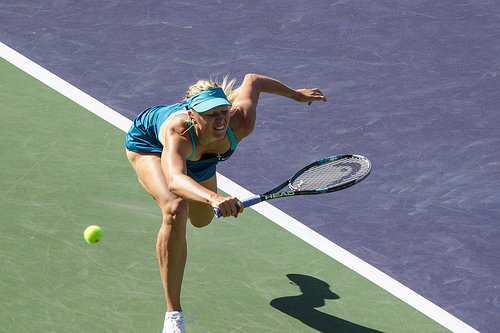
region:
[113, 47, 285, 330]
this is a person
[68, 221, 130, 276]
this is a ball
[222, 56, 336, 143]
this is a hand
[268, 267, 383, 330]
this is a shadow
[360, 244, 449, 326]
this is a line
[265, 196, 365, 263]
this is a line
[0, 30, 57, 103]
this is a line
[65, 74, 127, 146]
this is a line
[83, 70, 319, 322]
this is a person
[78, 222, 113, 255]
this is a ball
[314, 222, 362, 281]
a line on the road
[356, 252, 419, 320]
a line on the road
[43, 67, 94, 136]
a line on the road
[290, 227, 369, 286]
a line on the road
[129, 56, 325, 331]
A woman playing tennis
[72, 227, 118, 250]
A small green tennis ball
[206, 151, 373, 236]
A nlue handle tennis racket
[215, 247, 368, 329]
A green tennis court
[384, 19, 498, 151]
A grey tennis court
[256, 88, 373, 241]
A grey tennis court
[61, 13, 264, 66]
A grey tennis court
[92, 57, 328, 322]
this is a lady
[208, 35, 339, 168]
the hand of a lady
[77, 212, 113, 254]
this is a ball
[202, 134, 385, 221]
this is a racket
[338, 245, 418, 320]
a white line on the road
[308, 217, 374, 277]
a white line on the road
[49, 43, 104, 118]
a white line on the road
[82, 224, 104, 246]
green tennis ball in air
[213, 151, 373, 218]
tennis racket in woman's hand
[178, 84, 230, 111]
blue sun visor on woman's head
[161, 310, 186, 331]
white tennis shoe on woman's foot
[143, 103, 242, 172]
blue tank top shirt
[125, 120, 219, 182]
blue shorts on woman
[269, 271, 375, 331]
shadow of woman being cast on ground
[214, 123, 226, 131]
mouth on woman's face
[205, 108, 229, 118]
eyes on woman's face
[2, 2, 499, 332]
floor of tennis court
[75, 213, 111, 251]
A round tennis ball in the air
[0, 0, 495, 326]
A blue and green tennis court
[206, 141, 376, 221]
A tennis racket in a hand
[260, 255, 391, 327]
Shadow on the tennis court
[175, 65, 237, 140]
Blue visor on woman's head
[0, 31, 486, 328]
White line on the court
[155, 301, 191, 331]
A sneaker is white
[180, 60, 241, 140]
Woman has blonde hair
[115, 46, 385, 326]
A woman is playing tennis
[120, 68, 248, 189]
Tennis player wearing a blue outfit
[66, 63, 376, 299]
woman swinging at ball